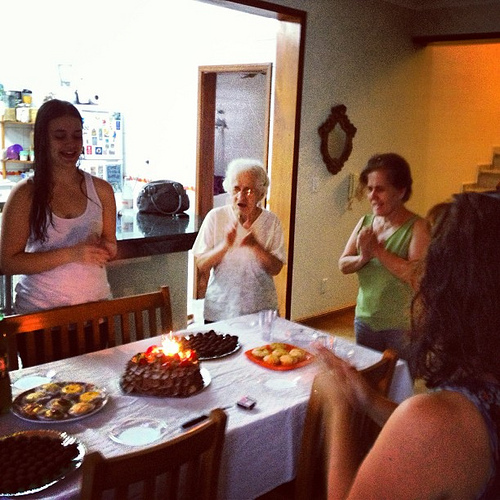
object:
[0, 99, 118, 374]
girl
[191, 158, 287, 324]
lady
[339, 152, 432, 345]
woman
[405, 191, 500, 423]
hair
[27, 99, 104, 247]
hair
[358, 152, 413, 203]
hair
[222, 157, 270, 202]
hair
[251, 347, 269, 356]
cookies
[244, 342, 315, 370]
plate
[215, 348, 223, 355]
cookies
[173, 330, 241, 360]
plate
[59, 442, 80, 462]
cookies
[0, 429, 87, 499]
plate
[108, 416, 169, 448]
plate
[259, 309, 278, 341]
cups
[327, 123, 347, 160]
mirror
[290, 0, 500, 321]
wall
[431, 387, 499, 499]
top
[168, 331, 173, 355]
candle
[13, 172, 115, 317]
top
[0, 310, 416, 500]
table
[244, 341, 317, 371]
dish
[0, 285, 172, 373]
chair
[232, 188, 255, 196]
glasses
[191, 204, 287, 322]
blouse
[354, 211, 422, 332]
top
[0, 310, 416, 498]
tablecloth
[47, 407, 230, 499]
chair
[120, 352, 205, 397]
cake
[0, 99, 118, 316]
people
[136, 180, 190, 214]
bag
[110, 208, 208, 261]
counter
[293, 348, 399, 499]
chair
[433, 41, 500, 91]
light